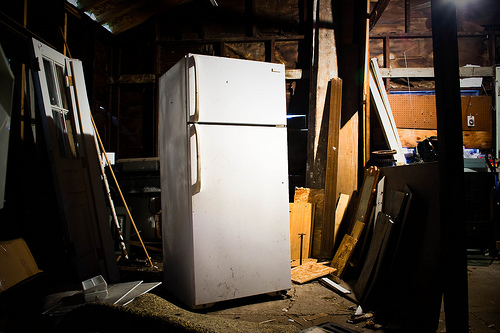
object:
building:
[0, 0, 499, 333]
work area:
[290, 0, 499, 333]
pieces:
[328, 231, 361, 282]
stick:
[50, 103, 75, 116]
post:
[260, 35, 280, 68]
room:
[1, 1, 500, 333]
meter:
[464, 113, 481, 128]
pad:
[55, 288, 304, 332]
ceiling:
[62, 0, 499, 36]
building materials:
[319, 74, 346, 264]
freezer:
[156, 52, 297, 310]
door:
[28, 36, 123, 283]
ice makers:
[79, 272, 114, 306]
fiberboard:
[289, 261, 340, 286]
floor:
[200, 262, 499, 333]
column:
[430, 0, 477, 332]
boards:
[113, 281, 163, 308]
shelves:
[98, 278, 148, 306]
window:
[41, 55, 61, 108]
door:
[183, 121, 295, 309]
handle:
[183, 123, 203, 197]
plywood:
[298, 256, 316, 279]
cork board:
[385, 91, 498, 135]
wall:
[70, 1, 500, 161]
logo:
[268, 66, 281, 75]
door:
[181, 52, 293, 127]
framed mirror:
[350, 164, 388, 226]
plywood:
[340, 136, 354, 166]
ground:
[196, 263, 499, 333]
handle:
[87, 106, 153, 265]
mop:
[66, 57, 130, 283]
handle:
[184, 54, 202, 124]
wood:
[322, 49, 334, 73]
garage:
[0, 0, 499, 333]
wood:
[76, 160, 94, 191]